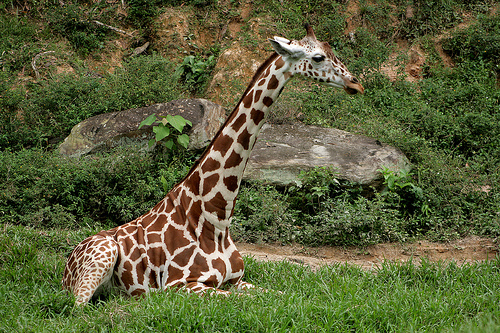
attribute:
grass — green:
[2, 257, 495, 331]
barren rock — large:
[49, 97, 419, 202]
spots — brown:
[118, 255, 148, 290]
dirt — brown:
[324, 238, 386, 259]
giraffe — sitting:
[41, 98, 373, 306]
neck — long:
[157, 53, 289, 219]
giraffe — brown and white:
[61, 111, 271, 308]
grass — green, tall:
[16, 277, 353, 331]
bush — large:
[362, 51, 484, 196]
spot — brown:
[196, 154, 220, 185]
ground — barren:
[298, 226, 393, 272]